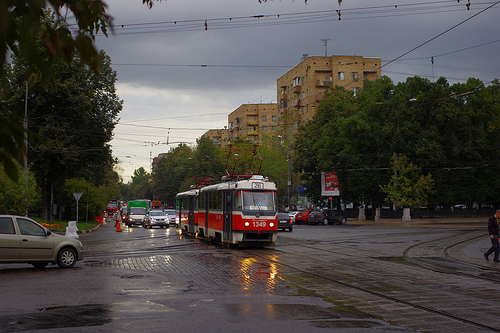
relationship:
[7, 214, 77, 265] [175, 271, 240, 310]
car on street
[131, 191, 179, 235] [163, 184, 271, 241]
vehicles behind train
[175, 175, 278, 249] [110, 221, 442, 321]
bus on street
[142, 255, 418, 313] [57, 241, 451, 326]
rain on street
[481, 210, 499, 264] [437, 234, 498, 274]
man beside street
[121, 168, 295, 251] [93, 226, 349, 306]
traffic on street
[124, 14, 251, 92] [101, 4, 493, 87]
clouds in sky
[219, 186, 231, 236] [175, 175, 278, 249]
door on bus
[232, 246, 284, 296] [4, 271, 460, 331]
light on pavement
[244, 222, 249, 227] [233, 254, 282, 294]
headlights has reflection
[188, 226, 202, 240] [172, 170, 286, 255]
light under bus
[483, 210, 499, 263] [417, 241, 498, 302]
man on road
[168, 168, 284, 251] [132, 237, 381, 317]
bus on road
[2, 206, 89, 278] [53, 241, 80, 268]
car has tire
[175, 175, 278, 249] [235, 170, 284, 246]
bus has front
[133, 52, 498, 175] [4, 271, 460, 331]
buildings in pavement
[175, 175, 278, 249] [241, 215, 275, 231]
bus has headlights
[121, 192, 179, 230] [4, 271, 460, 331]
cars on pavement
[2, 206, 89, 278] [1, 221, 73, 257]
car has side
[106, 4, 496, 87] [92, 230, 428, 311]
wires above street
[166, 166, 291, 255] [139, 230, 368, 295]
vehicle on street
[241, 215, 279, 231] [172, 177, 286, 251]
headlights on vehicle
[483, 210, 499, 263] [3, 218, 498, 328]
man walking on street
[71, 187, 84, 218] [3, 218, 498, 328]
sign beside street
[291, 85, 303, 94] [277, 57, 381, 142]
balcony on building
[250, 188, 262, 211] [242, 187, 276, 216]
wiper on window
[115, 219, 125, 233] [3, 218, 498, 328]
cone on street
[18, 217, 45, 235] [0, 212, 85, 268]
window in car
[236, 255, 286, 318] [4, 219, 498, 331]
reflection on pavement